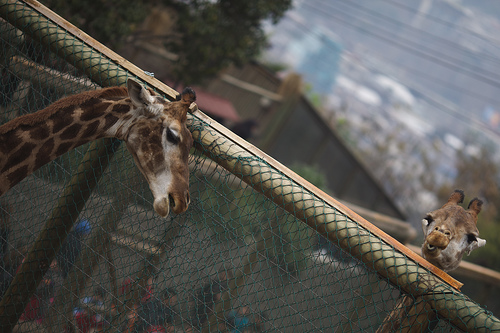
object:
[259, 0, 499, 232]
blue sky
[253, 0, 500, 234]
clouds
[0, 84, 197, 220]
giraffe